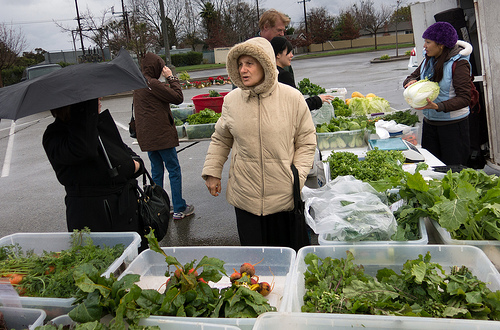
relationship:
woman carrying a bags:
[39, 100, 148, 232] [134, 158, 171, 244]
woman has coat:
[42, 100, 150, 254] [131, 50, 184, 150]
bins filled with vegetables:
[6, 237, 446, 317] [299, 258, 459, 307]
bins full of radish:
[290, 243, 500, 323] [98, 261, 268, 320]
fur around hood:
[216, 34, 282, 103] [218, 30, 298, 100]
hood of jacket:
[239, 35, 276, 73] [199, 35, 319, 215]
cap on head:
[418, 22, 463, 48] [413, 11, 464, 59]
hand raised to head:
[161, 67, 172, 79] [135, 50, 161, 81]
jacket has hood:
[199, 35, 318, 217] [224, 35, 278, 92]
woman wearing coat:
[42, 100, 150, 254] [131, 50, 184, 150]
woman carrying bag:
[42, 100, 150, 254] [297, 175, 399, 245]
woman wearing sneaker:
[42, 100, 150, 254] [173, 203, 195, 217]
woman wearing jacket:
[42, 100, 150, 254] [199, 35, 319, 215]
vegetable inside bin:
[349, 90, 367, 98] [115, 240, 297, 327]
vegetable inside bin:
[349, 90, 367, 98] [290, 235, 499, 327]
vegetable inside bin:
[40, 261, 102, 292] [115, 240, 297, 327]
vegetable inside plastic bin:
[349, 90, 367, 98] [285, 241, 499, 329]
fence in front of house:
[305, 31, 414, 54] [357, 20, 413, 35]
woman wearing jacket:
[400, 23, 484, 167] [199, 35, 318, 217]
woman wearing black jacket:
[42, 100, 150, 254] [40, 109, 146, 231]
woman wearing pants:
[42, 100, 150, 254] [235, 212, 292, 239]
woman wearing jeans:
[148, 44, 375, 236] [162, 179, 354, 239]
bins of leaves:
[290, 243, 500, 323] [319, 246, 459, 328]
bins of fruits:
[290, 243, 500, 323] [403, 78, 442, 111]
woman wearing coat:
[42, 100, 150, 254] [44, 98, 149, 238]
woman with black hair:
[42, 100, 150, 254] [271, 37, 296, 54]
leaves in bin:
[325, 259, 499, 314] [238, 233, 483, 324]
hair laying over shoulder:
[431, 42, 460, 80] [445, 48, 462, 76]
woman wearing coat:
[39, 100, 148, 232] [39, 122, 136, 229]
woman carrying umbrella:
[42, 100, 150, 254] [0, 48, 155, 123]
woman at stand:
[200, 36, 318, 247] [5, 235, 497, 318]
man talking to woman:
[256, 7, 288, 39] [400, 23, 484, 167]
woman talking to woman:
[42, 100, 150, 254] [400, 23, 484, 167]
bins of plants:
[290, 243, 500, 323] [120, 235, 267, 321]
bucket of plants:
[118, 244, 293, 321] [304, 246, 496, 315]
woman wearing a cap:
[413, 25, 483, 170] [422, 22, 459, 48]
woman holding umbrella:
[42, 100, 150, 254] [0, 48, 155, 123]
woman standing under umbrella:
[42, 100, 150, 254] [7, 61, 151, 120]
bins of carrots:
[290, 243, 500, 323] [6, 252, 60, 302]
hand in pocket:
[294, 169, 308, 198] [284, 160, 301, 193]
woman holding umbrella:
[42, 100, 150, 254] [17, 70, 133, 98]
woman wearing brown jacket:
[130, 52, 185, 228] [123, 51, 184, 153]